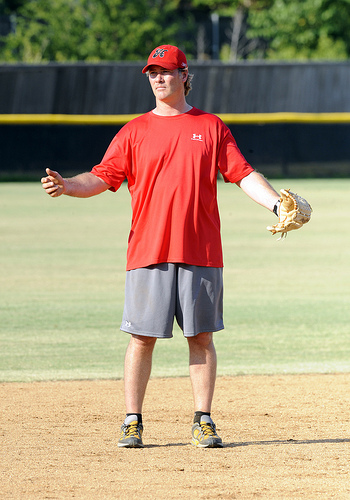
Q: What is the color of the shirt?
A: Red.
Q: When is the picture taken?
A: Daytime.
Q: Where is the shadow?
A: In the ground.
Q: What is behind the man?
A: Fence.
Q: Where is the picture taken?
A: At a softball game.